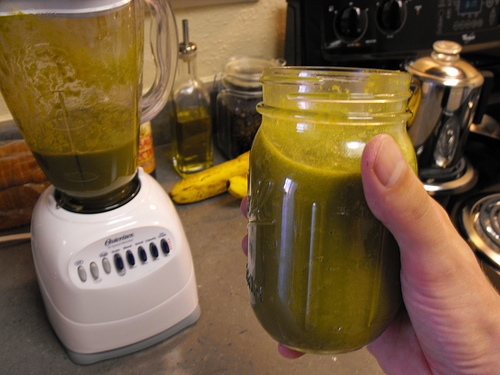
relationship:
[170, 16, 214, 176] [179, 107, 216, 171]
bottle of oil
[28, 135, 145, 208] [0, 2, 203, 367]
green liquid in blender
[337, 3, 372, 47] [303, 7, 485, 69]
control on stove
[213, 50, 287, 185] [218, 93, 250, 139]
container with dark contents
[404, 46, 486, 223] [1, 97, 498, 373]
kettle on stove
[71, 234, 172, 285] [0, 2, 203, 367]
buttons on blender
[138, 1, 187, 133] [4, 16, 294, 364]
handle on blender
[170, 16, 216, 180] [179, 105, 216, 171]
bottle of oil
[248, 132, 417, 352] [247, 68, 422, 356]
salsa in jar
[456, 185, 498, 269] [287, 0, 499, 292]
burner on stove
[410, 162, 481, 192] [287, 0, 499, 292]
burner on stove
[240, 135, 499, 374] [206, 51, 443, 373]
hand holding jar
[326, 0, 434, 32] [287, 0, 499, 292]
knobs on stove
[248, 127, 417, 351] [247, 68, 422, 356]
salsa in jar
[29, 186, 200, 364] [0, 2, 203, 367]
base on blender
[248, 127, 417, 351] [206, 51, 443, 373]
salsa in jar